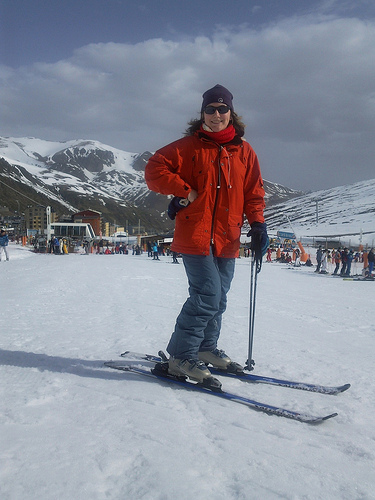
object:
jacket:
[139, 117, 279, 272]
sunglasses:
[198, 103, 238, 115]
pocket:
[171, 193, 210, 253]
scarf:
[186, 115, 243, 149]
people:
[137, 70, 285, 409]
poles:
[243, 243, 255, 375]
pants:
[158, 225, 242, 371]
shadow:
[0, 338, 218, 398]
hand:
[240, 222, 282, 272]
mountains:
[0, 117, 137, 257]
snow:
[0, 276, 90, 332]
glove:
[243, 214, 278, 269]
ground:
[2, 253, 374, 500]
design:
[216, 95, 225, 106]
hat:
[197, 80, 239, 117]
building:
[67, 203, 105, 243]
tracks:
[80, 236, 374, 499]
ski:
[97, 355, 338, 423]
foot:
[160, 348, 218, 387]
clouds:
[1, 1, 374, 137]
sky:
[1, 4, 373, 193]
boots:
[160, 347, 224, 389]